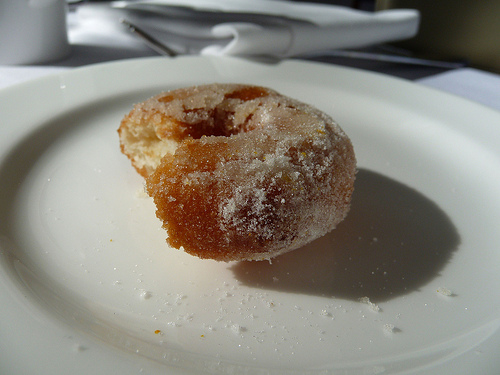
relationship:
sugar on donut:
[270, 113, 335, 193] [107, 64, 382, 279]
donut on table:
[111, 77, 375, 254] [9, 2, 498, 141]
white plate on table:
[64, 67, 496, 371] [331, 0, 498, 74]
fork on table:
[107, 19, 325, 64] [358, 0, 498, 81]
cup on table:
[0, 0, 73, 65] [345, 1, 498, 77]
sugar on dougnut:
[280, 197, 286, 203] [107, 74, 366, 269]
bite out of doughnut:
[117, 113, 185, 182] [61, 69, 373, 272]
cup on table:
[3, 0, 65, 60] [0, 64, 29, 83]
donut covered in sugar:
[117, 83, 355, 262] [68, 79, 471, 364]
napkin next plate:
[105, 0, 420, 59] [7, 45, 492, 345]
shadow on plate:
[383, 160, 461, 245] [356, 37, 479, 201]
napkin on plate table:
[61, 1, 421, 59] [0, 0, 499, 373]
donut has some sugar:
[117, 83, 355, 262] [157, 78, 323, 161]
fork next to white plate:
[120, 18, 178, 57] [0, 55, 500, 375]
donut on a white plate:
[117, 83, 355, 262] [0, 55, 500, 375]